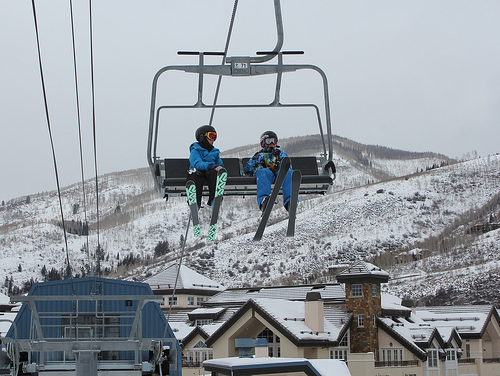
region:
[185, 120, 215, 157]
person wears black cap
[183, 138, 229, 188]
person wears blue coat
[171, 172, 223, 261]
black and blue skis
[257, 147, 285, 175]
person wears blue jacket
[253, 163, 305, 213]
person wears blue pants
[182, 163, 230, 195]
person wears black pants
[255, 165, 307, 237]
person wears black skis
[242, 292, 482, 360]
brown and tan house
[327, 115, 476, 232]
green and white mountain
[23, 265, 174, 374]
blue and grey building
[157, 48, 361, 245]
two people on ski lift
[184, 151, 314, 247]
two pair of skis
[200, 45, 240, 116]
cable above ski lift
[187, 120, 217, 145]
black helmet on skier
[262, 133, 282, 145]
goggles on skiers face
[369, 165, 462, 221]
snow on side of mountain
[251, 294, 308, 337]
snow on roof top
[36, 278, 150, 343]
blue wall on building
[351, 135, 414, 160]
trees on mountain top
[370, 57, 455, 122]
gray cover on daytime sky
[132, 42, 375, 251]
two skiers on a ski lift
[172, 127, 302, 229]
the skiers are sitting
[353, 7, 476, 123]
the sky is gray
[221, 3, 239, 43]
the cable above the lift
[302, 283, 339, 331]
the chimney on the roof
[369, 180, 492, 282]
the mountain is powdered with snow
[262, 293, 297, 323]
the snow on the roof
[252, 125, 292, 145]
the helmet on the skier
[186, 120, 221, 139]
the helmet on the skier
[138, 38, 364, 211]
the lift is moving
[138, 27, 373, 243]
a gray ski lift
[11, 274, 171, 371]
an angular blue metal building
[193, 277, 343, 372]
a white ski lodge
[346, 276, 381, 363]
a red and brown brick tower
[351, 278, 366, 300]
a window on the side of a tower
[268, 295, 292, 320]
snow on the rooftop of a lodge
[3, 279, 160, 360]
a metal portion of a ski lift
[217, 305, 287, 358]
a pointed white arch entryway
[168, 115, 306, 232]
two kids on a ski lift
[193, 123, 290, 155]
black helmets on two children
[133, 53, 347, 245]
two people on a ski lift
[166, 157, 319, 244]
two sets of skis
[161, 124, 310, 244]
two skiers wearing helmets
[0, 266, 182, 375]
bottom end of ski lift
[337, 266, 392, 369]
chimney of the building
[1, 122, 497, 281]
mountain in the background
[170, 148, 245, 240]
green marking on skis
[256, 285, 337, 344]
snow on a roof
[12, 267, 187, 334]
blue colored roof of lift terminal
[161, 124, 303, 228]
two skiers having a conversation